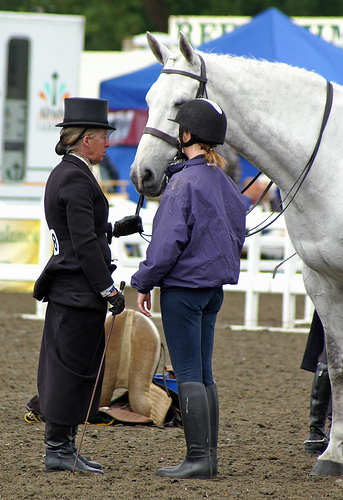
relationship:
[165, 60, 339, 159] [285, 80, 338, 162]
horse wearing harness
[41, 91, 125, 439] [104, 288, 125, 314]
woman wearing gloves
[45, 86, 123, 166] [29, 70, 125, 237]
head of person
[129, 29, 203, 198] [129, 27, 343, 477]
head of horse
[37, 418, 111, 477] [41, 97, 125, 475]
shoes on woman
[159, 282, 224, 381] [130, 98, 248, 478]
blue jeans on woman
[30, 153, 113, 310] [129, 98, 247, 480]
black jacket on women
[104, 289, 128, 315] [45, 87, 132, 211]
glove on person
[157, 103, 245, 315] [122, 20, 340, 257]
equiestrian by horse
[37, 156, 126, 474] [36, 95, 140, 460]
garment on woman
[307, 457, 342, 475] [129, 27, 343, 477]
shoe on horse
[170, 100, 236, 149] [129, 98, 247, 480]
helmet on women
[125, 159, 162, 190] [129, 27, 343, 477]
horse nose on horse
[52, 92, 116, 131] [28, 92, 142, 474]
hat on woman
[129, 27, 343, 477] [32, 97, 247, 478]
horse by women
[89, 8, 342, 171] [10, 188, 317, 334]
tent by fence